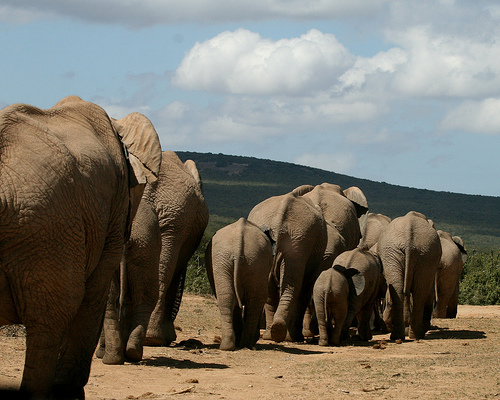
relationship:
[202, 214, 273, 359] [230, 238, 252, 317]
elephant has tail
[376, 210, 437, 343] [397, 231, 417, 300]
elephants has tail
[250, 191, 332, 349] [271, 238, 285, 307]
elephant has tail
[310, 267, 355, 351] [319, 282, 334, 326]
elephant of tail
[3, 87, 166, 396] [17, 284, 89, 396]
elephant has a leg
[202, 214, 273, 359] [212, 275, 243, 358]
elephant has a leg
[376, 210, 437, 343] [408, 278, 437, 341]
elephants has a leg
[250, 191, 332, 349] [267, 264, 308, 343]
elephant has a leg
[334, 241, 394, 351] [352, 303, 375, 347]
elephant has a leg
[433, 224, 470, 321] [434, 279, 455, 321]
elephant has leg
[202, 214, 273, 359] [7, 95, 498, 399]
animal in their natural surroundings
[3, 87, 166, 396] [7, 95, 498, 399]
elephant at rear of herd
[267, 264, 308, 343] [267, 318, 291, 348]
foot has bottom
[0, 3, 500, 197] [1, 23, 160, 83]
blue sky has patch color blue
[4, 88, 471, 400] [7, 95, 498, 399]
elephants walking in groups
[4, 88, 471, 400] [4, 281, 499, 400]
elephants walking on dirt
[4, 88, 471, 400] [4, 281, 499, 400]
elephants walking in field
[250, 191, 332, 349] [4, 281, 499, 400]
elephant walking on dirt field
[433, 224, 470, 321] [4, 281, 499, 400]
elephant walking in area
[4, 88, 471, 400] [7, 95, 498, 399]
elephants walking together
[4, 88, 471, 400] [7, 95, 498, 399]
elephants of different size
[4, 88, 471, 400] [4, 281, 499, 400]
elephants are in an area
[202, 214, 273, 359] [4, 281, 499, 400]
area with dirt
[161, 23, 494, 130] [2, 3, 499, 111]
clouds in a blue sky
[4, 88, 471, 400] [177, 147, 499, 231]
elephants in front bushes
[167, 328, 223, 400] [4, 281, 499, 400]
rocks on ground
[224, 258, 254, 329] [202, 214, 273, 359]
tail on elephant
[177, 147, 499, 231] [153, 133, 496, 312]
trees on hill